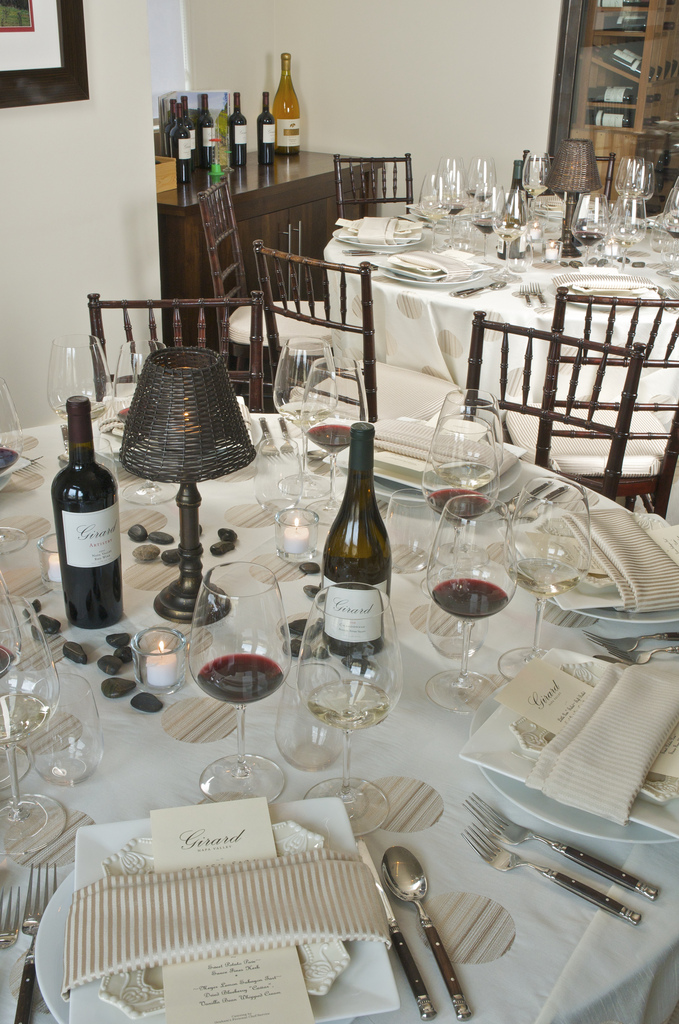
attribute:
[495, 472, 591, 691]
glass — wine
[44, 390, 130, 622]
bottle — large, Black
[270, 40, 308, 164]
bottle — giant, yellow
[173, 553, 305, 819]
glass — red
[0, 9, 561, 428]
wall — white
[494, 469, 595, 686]
wine — white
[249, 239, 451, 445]
chair — wooden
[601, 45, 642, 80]
bottles — angled, wine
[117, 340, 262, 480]
lampshade — black, wicker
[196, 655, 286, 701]
wine — red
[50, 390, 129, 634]
wine bottle — unopened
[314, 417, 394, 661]
wine bottle — green, unopened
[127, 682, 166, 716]
stone — black, small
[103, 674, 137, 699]
stone — black, small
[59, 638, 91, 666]
stone — black, small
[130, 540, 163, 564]
stone — black, small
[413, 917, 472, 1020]
grip — brown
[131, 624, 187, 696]
candle — lighted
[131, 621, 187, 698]
holder — glass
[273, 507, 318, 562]
holder — glass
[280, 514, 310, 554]
candle — lighted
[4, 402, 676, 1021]
table — white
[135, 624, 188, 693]
candle — white, small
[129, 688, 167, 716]
rock — smooth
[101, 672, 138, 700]
rock — smooth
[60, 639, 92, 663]
rock — smooth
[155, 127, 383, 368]
stand — wood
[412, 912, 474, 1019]
handle — wood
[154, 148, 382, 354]
table — brown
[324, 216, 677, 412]
tablecloth — white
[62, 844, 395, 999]
napkin — folded, striped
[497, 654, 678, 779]
menu — rectangular, white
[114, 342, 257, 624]
lamp — gray, brown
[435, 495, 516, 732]
wineglass — white table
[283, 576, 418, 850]
wineglass — white table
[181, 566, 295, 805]
wineglass — white table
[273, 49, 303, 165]
bottle — tall yellow tinted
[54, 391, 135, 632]
bottle — Black , wine 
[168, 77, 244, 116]
book — Opened 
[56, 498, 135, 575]
label — White 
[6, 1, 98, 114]
picture — dark framed 